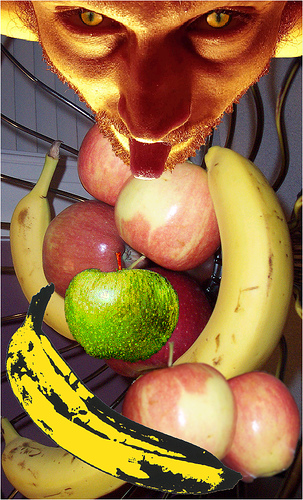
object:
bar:
[0, 109, 79, 165]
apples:
[122, 340, 235, 479]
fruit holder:
[0, 32, 301, 499]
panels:
[2, 37, 96, 157]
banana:
[5, 280, 243, 495]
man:
[8, 4, 297, 182]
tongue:
[127, 127, 172, 181]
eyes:
[192, 10, 251, 30]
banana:
[170, 144, 293, 392]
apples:
[113, 158, 217, 273]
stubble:
[174, 121, 199, 146]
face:
[32, 1, 273, 179]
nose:
[116, 48, 192, 146]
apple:
[40, 199, 146, 296]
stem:
[109, 245, 124, 276]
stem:
[159, 334, 178, 374]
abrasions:
[150, 174, 201, 250]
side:
[23, 34, 89, 115]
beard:
[78, 92, 225, 182]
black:
[0, 112, 79, 163]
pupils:
[210, 10, 223, 27]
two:
[123, 359, 301, 481]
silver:
[63, 356, 135, 409]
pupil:
[82, 9, 100, 26]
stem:
[35, 133, 63, 206]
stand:
[48, 320, 150, 439]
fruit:
[63, 250, 180, 365]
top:
[128, 366, 229, 419]